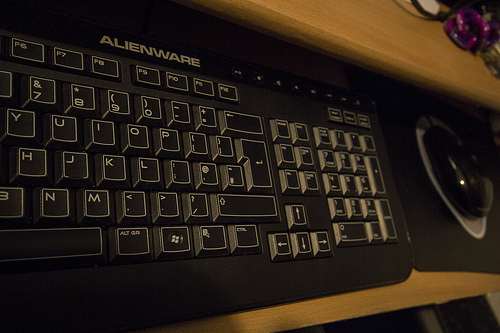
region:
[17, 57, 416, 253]
the keyboard is black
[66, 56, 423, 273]
the keyboard is black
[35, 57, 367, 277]
the keyboard is black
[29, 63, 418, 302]
keyboard's outline is white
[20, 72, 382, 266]
keyboard's outline is white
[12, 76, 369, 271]
keyboard's outline is white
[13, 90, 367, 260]
keyboard kept in the table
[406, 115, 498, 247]
black color mouse kept in the mouse pad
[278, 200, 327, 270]
arrow keys in the keyboard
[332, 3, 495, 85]
brown color computer table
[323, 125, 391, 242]
numeric keys in the keyboard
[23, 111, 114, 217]
alphabet keys in the keyboard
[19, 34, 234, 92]
function keys in the keyboard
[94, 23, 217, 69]
brand name of the keyboard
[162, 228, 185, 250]
windows key in the keyboard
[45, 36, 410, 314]
Key board is black color.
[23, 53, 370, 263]
Letters are white color.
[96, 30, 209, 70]
Alienware is the brand name.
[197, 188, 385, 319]
Key board is in the table.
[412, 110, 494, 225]
Mouse is black color.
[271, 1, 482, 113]
Table is brown color.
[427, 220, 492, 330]
Mouse pad is in the table.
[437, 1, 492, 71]
Pen stand is purple color.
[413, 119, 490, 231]
computer mouse is here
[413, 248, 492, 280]
mousepad on the desk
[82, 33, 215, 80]
the keyboard is alienware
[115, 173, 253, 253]
keys on the keyboard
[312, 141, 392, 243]
number keys on keyboard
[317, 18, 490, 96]
upper half of desk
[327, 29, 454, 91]
desk is made of wood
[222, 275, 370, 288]
the keyboard is black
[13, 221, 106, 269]
space bar on the keyboard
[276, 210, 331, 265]
arrow keys on keyboard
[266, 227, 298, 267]
this is a key on the key board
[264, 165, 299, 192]
this is a key on the key board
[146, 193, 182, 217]
this is a key on the key board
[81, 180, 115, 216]
this is a key on the key board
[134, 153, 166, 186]
this is a key on the key board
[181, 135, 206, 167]
this is a key on the key board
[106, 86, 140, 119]
this is a key on the key board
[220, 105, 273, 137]
this is a key on the key board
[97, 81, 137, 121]
this is a key on the key board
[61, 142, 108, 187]
this is a key on the key board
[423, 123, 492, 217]
the mouse is black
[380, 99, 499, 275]
the mousepad under the mouse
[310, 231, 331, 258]
the arrow on the key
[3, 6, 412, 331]
the keyboard is black and white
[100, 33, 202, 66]
the word ALIENWARE is white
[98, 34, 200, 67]
the word ALIENWARE is all upper case letters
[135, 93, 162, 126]
the number 0 on the key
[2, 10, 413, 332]
the white accent coloring on the keyboard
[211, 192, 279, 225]
the arrow on the key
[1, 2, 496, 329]
the keyboard next to the mouse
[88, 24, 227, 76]
this is the Alienware typographic logo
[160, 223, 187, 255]
the windows key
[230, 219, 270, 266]
the control key